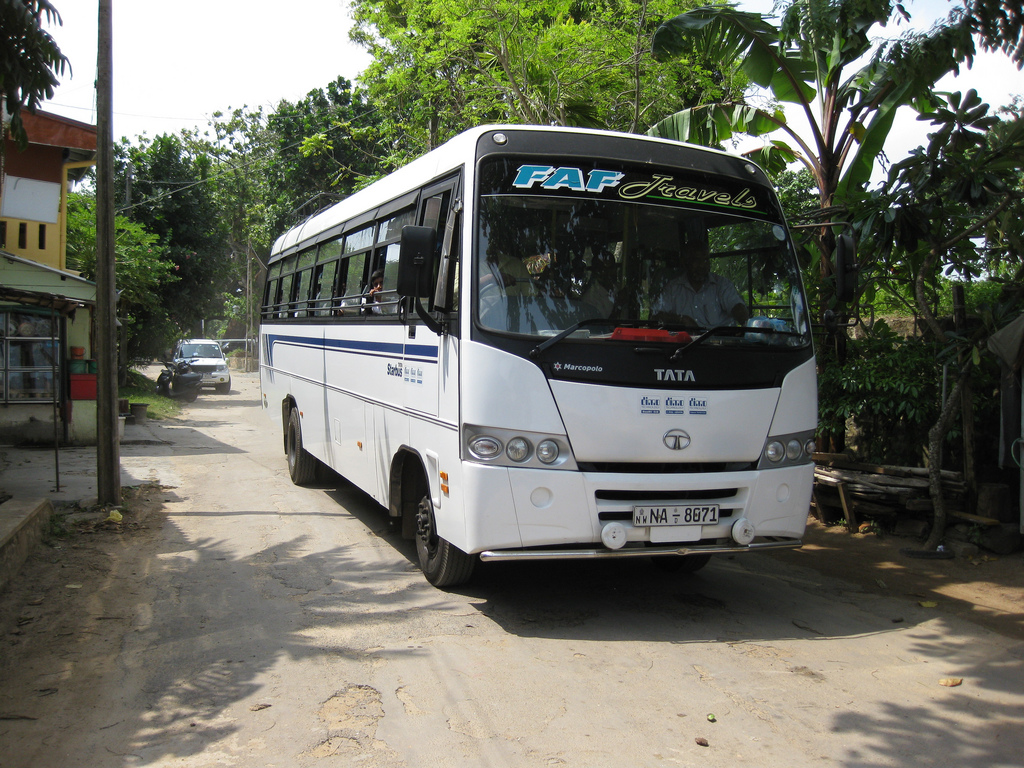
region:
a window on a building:
[0, 235, 20, 267]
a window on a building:
[35, 218, 46, 256]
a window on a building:
[10, 314, 56, 337]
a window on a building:
[16, 339, 62, 360]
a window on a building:
[10, 370, 53, 409]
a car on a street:
[142, 326, 232, 387]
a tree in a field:
[59, 194, 178, 372]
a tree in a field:
[122, 134, 230, 350]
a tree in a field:
[193, 115, 273, 332]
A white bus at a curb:
[223, 118, 852, 590]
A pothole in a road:
[309, 680, 390, 742]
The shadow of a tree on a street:
[0, 534, 463, 766]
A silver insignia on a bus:
[654, 421, 696, 456]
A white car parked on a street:
[173, 332, 232, 390]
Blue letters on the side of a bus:
[372, 352, 433, 390]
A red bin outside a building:
[62, 362, 107, 402]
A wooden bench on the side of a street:
[814, 387, 979, 558]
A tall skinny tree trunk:
[87, 4, 133, 516]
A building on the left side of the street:
[5, 83, 148, 476]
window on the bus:
[411, 217, 459, 315]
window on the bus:
[257, 262, 281, 313]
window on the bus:
[393, 179, 457, 219]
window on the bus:
[330, 230, 378, 253]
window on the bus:
[280, 275, 318, 307]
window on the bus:
[705, 208, 770, 251]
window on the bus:
[716, 304, 778, 355]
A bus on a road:
[265, 126, 829, 592]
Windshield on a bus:
[476, 184, 808, 353]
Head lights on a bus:
[458, 421, 577, 478]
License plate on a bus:
[616, 490, 728, 536]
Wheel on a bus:
[407, 462, 477, 593]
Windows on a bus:
[255, 247, 442, 328]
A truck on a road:
[167, 333, 231, 395]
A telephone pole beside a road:
[84, 4, 152, 499]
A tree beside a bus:
[632, 9, 1019, 468]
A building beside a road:
[0, 96, 93, 448]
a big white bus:
[233, 116, 835, 591]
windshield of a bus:
[465, 127, 830, 366]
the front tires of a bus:
[404, 477, 472, 604]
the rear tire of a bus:
[268, 375, 330, 500]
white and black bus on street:
[242, 112, 830, 622]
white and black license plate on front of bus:
[620, 495, 729, 538]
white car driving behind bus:
[164, 330, 237, 403]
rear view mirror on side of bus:
[385, 217, 462, 348]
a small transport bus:
[253, 128, 817, 587]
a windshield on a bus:
[472, 189, 806, 348]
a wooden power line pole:
[96, 0, 119, 511]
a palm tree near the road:
[643, 2, 973, 455]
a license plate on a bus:
[633, 504, 723, 527]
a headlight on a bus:
[537, 438, 561, 467]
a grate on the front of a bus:
[578, 462, 744, 527]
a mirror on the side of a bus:
[402, 225, 431, 296]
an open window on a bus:
[370, 246, 386, 297]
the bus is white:
[291, 181, 737, 594]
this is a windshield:
[425, 137, 783, 385]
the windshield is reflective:
[482, 168, 765, 383]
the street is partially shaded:
[83, 483, 377, 715]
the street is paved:
[168, 579, 524, 745]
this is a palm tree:
[741, 17, 967, 515]